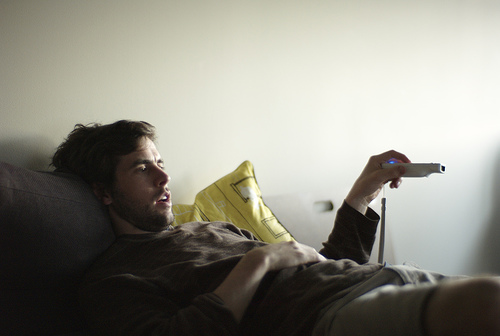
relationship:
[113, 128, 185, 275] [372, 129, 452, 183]
man holding remote control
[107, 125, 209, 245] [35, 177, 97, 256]
head on pillow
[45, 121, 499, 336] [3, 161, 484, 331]
man laying on bed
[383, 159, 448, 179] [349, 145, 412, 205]
remote in man's hand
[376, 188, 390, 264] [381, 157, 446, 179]
cord hanging from remote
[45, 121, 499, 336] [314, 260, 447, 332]
man wearing underwear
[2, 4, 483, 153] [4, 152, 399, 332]
wall by bed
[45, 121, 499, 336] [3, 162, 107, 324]
man resting on black pillow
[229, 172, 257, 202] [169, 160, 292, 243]
pattern on pillow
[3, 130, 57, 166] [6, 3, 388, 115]
shadow on wall